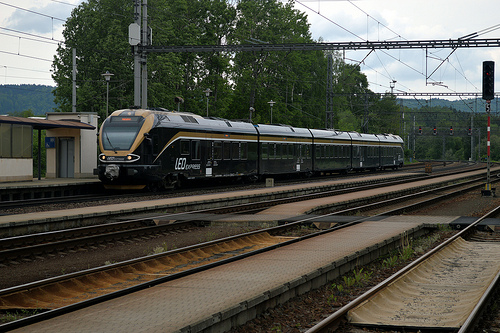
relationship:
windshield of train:
[100, 125, 148, 151] [89, 106, 414, 191]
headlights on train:
[96, 153, 140, 163] [89, 106, 414, 191]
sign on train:
[110, 114, 134, 125] [89, 106, 414, 191]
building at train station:
[7, 96, 103, 184] [7, 25, 486, 231]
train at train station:
[89, 106, 414, 191] [7, 25, 486, 231]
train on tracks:
[89, 106, 414, 191] [191, 181, 490, 322]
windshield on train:
[100, 125, 148, 151] [89, 106, 414, 191]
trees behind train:
[41, 0, 406, 117] [89, 106, 414, 191]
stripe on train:
[144, 131, 402, 160] [89, 106, 414, 191]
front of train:
[90, 117, 154, 184] [89, 106, 414, 191]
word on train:
[175, 153, 189, 173] [89, 106, 414, 191]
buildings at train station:
[7, 96, 103, 184] [7, 25, 486, 231]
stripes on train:
[150, 133, 400, 149] [89, 106, 414, 191]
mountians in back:
[0, 77, 494, 115] [3, 17, 488, 111]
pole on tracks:
[482, 57, 499, 195] [191, 181, 490, 322]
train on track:
[89, 106, 414, 191] [1, 155, 427, 204]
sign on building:
[42, 135, 64, 150] [7, 96, 103, 184]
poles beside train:
[122, 13, 161, 105] [89, 106, 414, 191]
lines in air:
[10, 5, 72, 77] [2, 9, 112, 89]